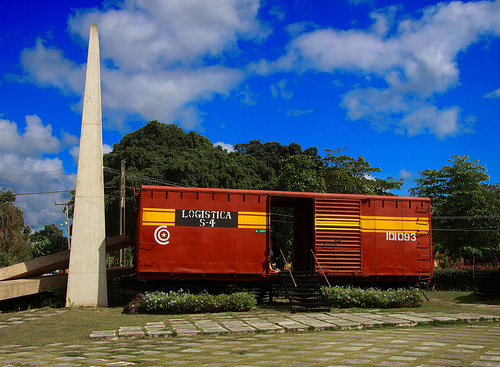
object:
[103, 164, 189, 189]
wires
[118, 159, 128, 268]
pole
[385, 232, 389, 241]
lettering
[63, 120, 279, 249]
trees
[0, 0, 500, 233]
clouds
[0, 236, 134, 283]
slabs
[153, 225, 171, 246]
target spot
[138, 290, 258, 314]
bushes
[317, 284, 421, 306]
bushes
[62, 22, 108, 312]
pointy monument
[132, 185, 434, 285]
boxcar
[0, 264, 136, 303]
wood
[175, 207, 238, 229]
logo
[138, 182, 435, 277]
boxcar side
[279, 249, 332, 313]
stairs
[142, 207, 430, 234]
stripes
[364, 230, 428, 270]
background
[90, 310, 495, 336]
pathway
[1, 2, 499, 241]
sky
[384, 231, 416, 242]
101093